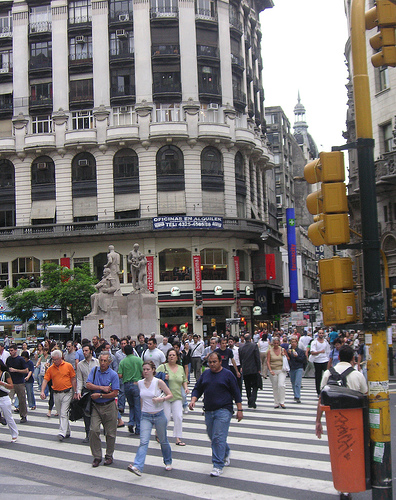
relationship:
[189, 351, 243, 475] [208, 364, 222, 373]
man has neck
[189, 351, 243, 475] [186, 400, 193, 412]
man has hand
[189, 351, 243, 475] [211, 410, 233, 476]
man has leg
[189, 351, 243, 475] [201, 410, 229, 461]
man has leg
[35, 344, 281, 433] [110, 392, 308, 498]
people walking on crosswalk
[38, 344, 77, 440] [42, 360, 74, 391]
man wearing shirt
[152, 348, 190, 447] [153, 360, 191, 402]
people wearing shirt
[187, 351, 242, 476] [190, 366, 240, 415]
man wearing shirt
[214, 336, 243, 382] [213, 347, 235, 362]
man wearing shirt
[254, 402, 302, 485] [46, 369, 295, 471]
strips painted on street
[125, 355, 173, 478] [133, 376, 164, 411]
people wearing shirt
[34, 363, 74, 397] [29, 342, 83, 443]
orange shirt on man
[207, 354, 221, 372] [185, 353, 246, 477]
head on man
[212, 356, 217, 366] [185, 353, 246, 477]
eye of man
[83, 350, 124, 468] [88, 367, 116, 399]
man wearing blue shirt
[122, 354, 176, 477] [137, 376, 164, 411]
woman wearing shirt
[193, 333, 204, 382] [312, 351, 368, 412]
man wearing shirt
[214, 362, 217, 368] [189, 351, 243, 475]
chin of man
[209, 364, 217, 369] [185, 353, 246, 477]
mouth of man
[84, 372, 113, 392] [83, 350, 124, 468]
arm of man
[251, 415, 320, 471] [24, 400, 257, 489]
white lines on road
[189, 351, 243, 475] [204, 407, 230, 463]
man wearing jeans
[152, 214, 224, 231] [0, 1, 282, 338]
sign on building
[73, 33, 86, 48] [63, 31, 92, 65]
air conditioner in window